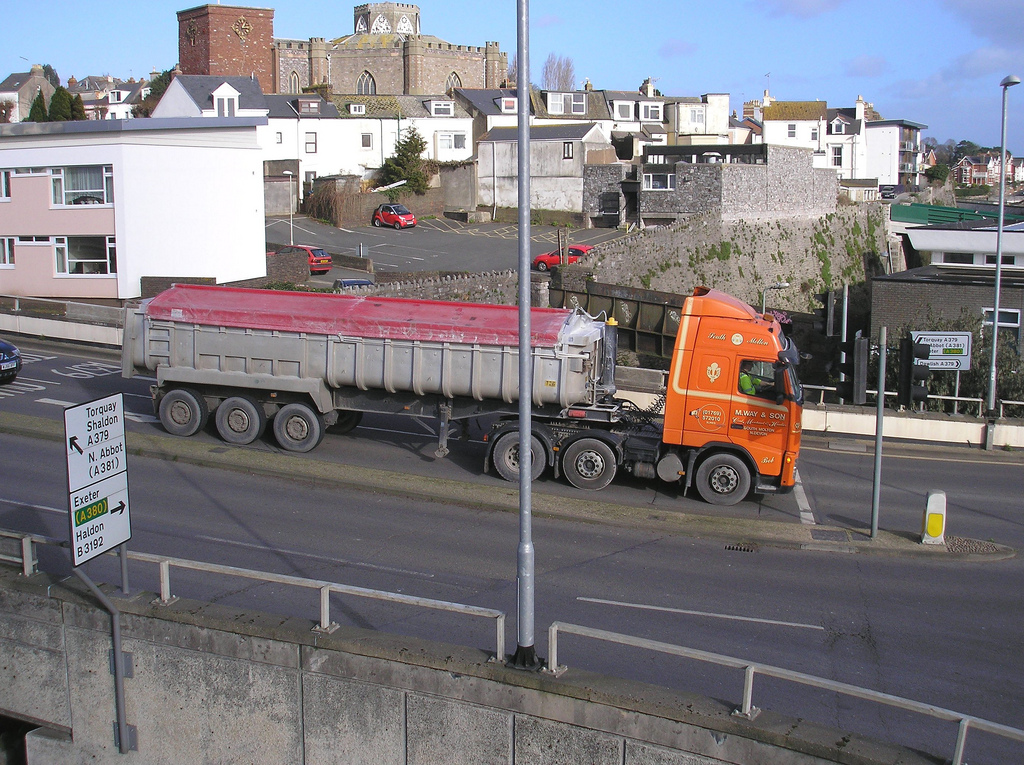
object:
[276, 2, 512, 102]
building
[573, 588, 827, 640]
lines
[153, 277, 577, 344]
tarp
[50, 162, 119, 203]
window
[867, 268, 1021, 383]
building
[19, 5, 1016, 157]
sky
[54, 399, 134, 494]
sign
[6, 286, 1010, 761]
road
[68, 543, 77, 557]
character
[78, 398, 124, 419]
character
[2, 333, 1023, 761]
road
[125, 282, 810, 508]
large truck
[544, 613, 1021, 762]
rails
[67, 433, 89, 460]
arrow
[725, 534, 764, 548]
gutter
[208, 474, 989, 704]
road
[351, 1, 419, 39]
tower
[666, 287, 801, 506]
cab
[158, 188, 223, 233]
wall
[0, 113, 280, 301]
building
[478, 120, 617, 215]
houses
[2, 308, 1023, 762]
highway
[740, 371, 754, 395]
shirt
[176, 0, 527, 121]
bricked castle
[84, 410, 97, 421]
letters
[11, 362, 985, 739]
highway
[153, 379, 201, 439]
wheels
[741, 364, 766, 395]
driver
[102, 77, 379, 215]
building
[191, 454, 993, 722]
road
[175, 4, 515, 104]
building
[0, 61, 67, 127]
building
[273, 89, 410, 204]
building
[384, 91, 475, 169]
building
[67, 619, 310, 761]
structure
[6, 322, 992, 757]
ground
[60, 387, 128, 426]
top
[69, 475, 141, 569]
sign